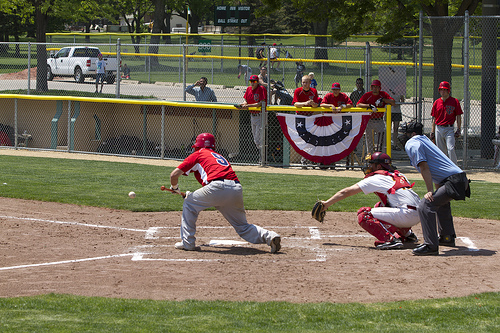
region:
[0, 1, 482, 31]
green leaves of trees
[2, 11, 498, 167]
chain link fence and poles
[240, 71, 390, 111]
boys leaning on yellow post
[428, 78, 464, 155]
standing boy in uniform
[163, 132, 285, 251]
player bending forward with bat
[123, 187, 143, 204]
white baseball in mid air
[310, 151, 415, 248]
squatting catcher with extended arm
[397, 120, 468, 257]
umpire with hand on leg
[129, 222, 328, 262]
white lines designating batter's box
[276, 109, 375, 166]
red, white and blue banner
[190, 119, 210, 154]
batter has red helmet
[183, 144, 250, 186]
red and blue shirt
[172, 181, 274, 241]
grey and black pants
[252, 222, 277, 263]
batter has white shoes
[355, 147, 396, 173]
catcher has dark red helmet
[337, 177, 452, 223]
catcher has white shirt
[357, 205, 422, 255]
catcher has red shinguards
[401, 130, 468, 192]
umpire has blue shirt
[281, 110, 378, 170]
red white and blue flag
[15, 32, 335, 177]
metal fence near dugout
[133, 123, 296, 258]
batter standing in the dirt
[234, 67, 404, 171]
players standing in the dugout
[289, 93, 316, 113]
arms resting on the fence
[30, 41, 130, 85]
white truck on the road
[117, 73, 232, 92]
row of concrete parking blocks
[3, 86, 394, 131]
bright yellow line on the top of the fence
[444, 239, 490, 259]
shadow from the umpire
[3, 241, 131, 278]
white line in the dirt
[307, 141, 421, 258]
catcher crouched down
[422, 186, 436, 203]
hand on the leg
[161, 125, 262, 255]
this is a baseball player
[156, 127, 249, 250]
he is swinging the bat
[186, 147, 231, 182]
the jersey is red in color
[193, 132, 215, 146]
he is wearing a helmet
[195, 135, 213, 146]
the helmet is red in color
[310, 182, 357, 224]
the hand is in front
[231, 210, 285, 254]
the leg is behind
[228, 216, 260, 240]
the knee is bent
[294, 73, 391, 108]
these are the substitutes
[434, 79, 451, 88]
the helmet is red in color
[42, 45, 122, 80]
A white pickup truck.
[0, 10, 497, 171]
A grey chain linked fence.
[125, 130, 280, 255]
A guy about to hit a baseball.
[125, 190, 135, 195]
A baseball.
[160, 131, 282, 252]
A batter.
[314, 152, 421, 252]
A catcher.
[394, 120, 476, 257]
An umpire.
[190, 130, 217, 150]
A red helmet.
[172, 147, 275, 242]
A red, white, blue, and grey baseball uniform.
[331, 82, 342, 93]
A red and blue ball cap.